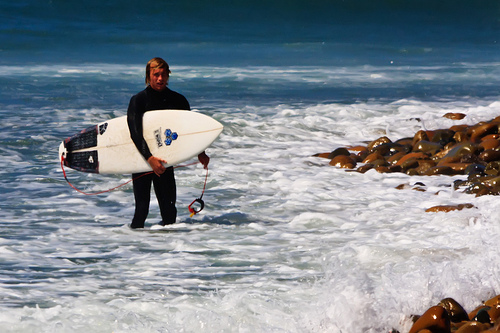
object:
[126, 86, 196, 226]
wetsuit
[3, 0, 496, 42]
sky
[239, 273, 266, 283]
ripples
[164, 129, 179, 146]
design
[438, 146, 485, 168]
rock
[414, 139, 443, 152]
rock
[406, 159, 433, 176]
rock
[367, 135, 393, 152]
rock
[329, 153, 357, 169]
rock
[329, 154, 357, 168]
brown rocks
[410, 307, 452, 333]
brown rocks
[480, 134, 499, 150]
rocks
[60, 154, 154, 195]
rope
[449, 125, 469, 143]
rocks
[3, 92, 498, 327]
waves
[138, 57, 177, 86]
hair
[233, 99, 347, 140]
foamy surf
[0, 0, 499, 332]
water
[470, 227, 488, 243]
ripples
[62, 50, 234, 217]
man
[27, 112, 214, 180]
surf board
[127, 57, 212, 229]
surfer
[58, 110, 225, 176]
board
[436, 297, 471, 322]
rocks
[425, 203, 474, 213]
rocks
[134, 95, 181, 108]
black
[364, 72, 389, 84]
waves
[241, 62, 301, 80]
waves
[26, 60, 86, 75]
waves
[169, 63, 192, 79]
waves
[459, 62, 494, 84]
waves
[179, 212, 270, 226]
shadow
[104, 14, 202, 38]
clouds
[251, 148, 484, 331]
surf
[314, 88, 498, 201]
shore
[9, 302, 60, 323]
ripples